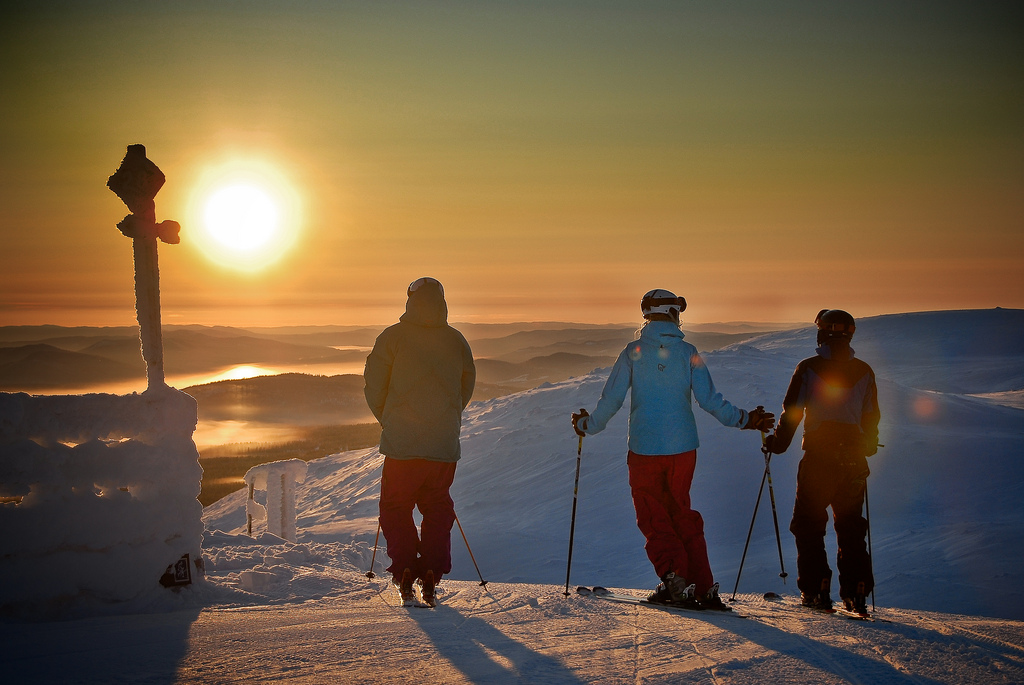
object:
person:
[365, 277, 475, 584]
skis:
[394, 580, 437, 608]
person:
[570, 289, 773, 600]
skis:
[577, 586, 749, 619]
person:
[761, 309, 884, 611]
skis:
[762, 592, 875, 622]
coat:
[577, 321, 750, 456]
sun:
[183, 158, 304, 274]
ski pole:
[365, 523, 381, 580]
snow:
[0, 308, 1024, 685]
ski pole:
[454, 511, 489, 590]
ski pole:
[562, 436, 582, 598]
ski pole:
[731, 454, 772, 600]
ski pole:
[866, 480, 877, 617]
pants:
[380, 455, 459, 583]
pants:
[627, 448, 715, 597]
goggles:
[641, 296, 687, 312]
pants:
[789, 452, 872, 593]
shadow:
[406, 606, 586, 685]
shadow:
[662, 607, 949, 685]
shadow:
[830, 612, 1024, 669]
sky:
[0, 0, 1024, 326]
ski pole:
[759, 431, 787, 583]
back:
[380, 322, 463, 462]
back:
[629, 339, 701, 455]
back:
[802, 355, 871, 449]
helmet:
[814, 309, 855, 344]